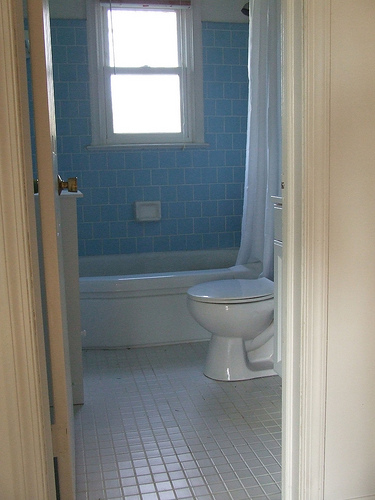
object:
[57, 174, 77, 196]
door knob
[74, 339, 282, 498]
tiles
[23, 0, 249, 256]
wall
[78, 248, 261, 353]
bathtub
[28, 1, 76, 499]
door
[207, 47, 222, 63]
tile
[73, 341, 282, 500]
floor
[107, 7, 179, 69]
blinds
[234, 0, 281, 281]
curtain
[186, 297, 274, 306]
toilet seat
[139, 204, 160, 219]
soap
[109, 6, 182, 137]
picture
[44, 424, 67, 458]
hinge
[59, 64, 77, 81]
blue tiles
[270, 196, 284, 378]
vanity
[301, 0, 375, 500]
wall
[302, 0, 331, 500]
moulding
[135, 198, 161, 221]
soap dish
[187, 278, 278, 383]
toilet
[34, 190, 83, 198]
counter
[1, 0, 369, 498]
picture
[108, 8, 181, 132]
day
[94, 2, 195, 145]
window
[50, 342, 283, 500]
squares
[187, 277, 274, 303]
lid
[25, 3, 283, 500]
bathroom